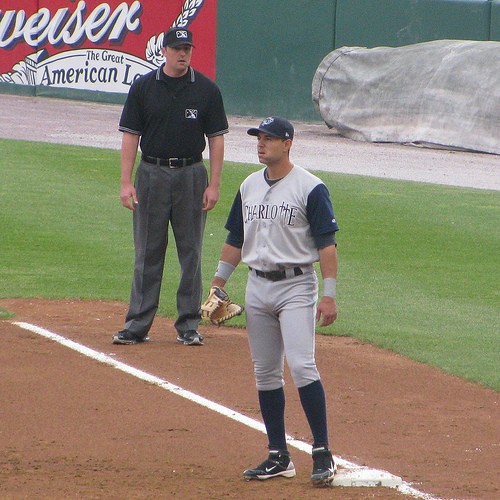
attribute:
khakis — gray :
[122, 151, 202, 340]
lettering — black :
[245, 197, 365, 232]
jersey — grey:
[207, 159, 355, 296]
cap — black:
[160, 25, 197, 48]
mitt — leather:
[199, 289, 241, 326]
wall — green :
[228, 4, 316, 114]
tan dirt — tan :
[0, 93, 496, 196]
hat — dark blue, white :
[247, 115, 297, 142]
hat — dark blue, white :
[159, 25, 198, 50]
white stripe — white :
[15, 350, 245, 431]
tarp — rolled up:
[305, 40, 495, 152]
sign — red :
[0, 2, 227, 95]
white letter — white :
[100, 0, 142, 47]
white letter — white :
[83, 4, 111, 44]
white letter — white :
[59, 0, 89, 53]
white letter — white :
[18, 7, 48, 47]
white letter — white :
[0, 8, 29, 47]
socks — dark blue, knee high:
[256, 380, 331, 450]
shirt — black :
[119, 63, 230, 156]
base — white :
[328, 465, 405, 490]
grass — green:
[1, 131, 498, 376]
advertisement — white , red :
[3, 2, 232, 120]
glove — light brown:
[195, 283, 242, 329]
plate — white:
[332, 466, 403, 489]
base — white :
[332, 466, 404, 493]